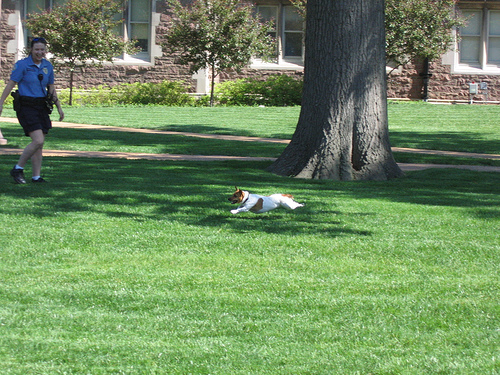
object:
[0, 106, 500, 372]
grass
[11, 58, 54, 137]
uniform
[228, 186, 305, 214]
dog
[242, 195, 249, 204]
collar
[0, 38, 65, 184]
woman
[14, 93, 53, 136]
shorts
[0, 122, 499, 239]
shadow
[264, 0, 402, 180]
tree